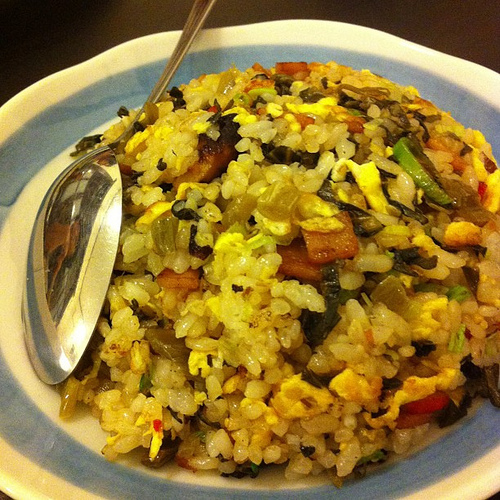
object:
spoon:
[22, 2, 215, 385]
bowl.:
[0, 18, 500, 500]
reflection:
[43, 146, 123, 386]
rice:
[297, 284, 325, 315]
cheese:
[137, 182, 201, 224]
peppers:
[392, 137, 453, 206]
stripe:
[1, 40, 500, 234]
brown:
[300, 211, 359, 264]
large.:
[19, 146, 124, 385]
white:
[1, 16, 500, 143]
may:
[277, 238, 325, 282]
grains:
[334, 436, 362, 479]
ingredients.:
[155, 268, 201, 293]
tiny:
[244, 379, 273, 399]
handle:
[108, 1, 217, 151]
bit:
[402, 393, 449, 414]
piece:
[188, 348, 219, 379]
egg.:
[187, 350, 214, 378]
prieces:
[389, 137, 451, 204]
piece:
[144, 323, 192, 376]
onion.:
[144, 326, 191, 361]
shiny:
[19, 1, 216, 387]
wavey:
[1, 18, 499, 163]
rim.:
[1, 16, 500, 163]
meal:
[171, 121, 239, 192]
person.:
[43, 214, 83, 292]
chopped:
[144, 327, 192, 357]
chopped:
[393, 137, 454, 206]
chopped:
[398, 388, 449, 416]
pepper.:
[400, 390, 451, 415]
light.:
[67, 200, 122, 356]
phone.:
[44, 215, 62, 272]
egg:
[270, 373, 333, 422]